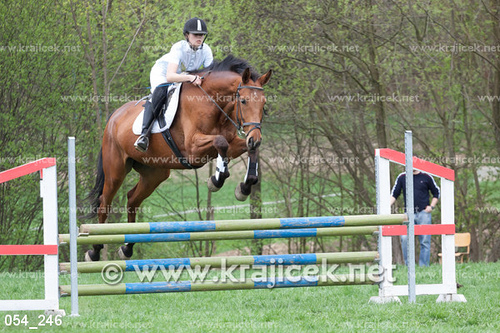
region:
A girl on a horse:
[135, 9, 268, 111]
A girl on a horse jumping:
[126, 10, 293, 293]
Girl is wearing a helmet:
[179, 15, 210, 45]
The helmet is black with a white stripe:
[178, 14, 211, 36]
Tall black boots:
[141, 81, 157, 160]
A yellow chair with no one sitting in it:
[426, 219, 476, 270]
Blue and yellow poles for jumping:
[71, 207, 390, 294]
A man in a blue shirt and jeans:
[383, 123, 451, 300]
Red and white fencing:
[1, 147, 61, 330]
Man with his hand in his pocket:
[411, 158, 443, 223]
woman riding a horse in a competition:
[86, 17, 269, 258]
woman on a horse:
[137, 16, 212, 151]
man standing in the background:
[392, 167, 439, 267]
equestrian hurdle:
[0, 136, 464, 313]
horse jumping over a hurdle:
[87, 58, 275, 265]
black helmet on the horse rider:
[183, 19, 208, 36]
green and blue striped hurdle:
[79, 211, 414, 231]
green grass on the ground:
[0, 263, 497, 331]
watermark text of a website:
[99, 260, 395, 288]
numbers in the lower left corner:
[3, 315, 64, 327]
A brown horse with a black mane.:
[83, 50, 276, 266]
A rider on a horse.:
[130, 14, 217, 154]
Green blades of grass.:
[331, 305, 488, 331]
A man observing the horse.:
[387, 153, 442, 266]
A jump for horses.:
[0, 125, 469, 315]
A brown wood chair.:
[437, 229, 471, 266]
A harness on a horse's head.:
[232, 83, 270, 135]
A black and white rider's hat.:
[182, 15, 212, 52]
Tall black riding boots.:
[132, 98, 157, 151]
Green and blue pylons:
[60, 208, 407, 300]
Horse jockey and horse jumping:
[28, 11, 324, 299]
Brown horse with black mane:
[201, 30, 283, 152]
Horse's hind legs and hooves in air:
[46, 13, 192, 268]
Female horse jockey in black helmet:
[135, 7, 217, 148]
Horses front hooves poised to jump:
[176, 152, 320, 208]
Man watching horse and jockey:
[81, 5, 458, 310]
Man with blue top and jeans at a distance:
[357, 130, 470, 318]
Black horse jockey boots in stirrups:
[121, 62, 177, 147]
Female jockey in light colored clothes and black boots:
[131, 4, 226, 159]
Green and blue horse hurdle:
[49, 155, 424, 310]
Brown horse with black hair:
[65, 15, 298, 231]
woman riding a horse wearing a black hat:
[76, 20, 273, 192]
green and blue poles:
[59, 203, 450, 304]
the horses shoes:
[50, 158, 295, 248]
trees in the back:
[26, 15, 96, 91]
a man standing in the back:
[375, 120, 450, 280]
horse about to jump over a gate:
[62, 36, 278, 186]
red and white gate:
[350, 126, 460, 256]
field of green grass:
[72, 261, 472, 326]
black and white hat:
[174, 10, 219, 50]